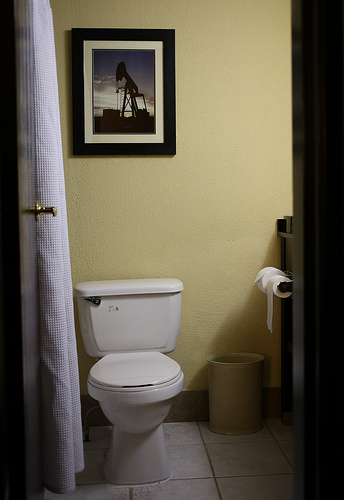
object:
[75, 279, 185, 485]
toilet paper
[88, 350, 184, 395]
seat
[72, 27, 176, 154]
picture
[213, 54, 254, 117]
wall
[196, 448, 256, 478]
floor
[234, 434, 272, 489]
tiles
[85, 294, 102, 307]
handle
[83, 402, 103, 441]
wire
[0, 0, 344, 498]
bathroom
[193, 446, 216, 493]
tiling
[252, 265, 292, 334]
two rolls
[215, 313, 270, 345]
shadow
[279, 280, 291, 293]
holders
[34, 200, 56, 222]
doorknob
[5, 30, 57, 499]
door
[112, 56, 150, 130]
oil rig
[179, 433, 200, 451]
flooring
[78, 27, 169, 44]
frame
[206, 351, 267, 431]
wastebasket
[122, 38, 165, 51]
border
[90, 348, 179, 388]
lid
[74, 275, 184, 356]
toilet tank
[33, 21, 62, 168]
shower curtain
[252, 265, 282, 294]
toilet rolls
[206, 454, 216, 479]
grout